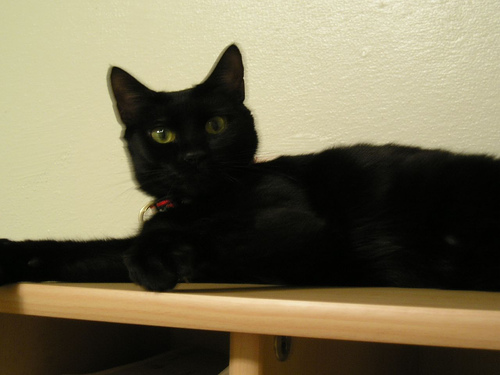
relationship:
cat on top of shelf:
[1, 44, 498, 295] [0, 277, 499, 352]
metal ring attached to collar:
[140, 202, 158, 223] [150, 197, 195, 209]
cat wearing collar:
[1, 44, 498, 295] [150, 197, 195, 209]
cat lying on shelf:
[1, 44, 498, 295] [0, 277, 499, 352]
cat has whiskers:
[1, 44, 498, 295] [98, 171, 181, 198]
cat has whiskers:
[1, 44, 498, 295] [207, 145, 286, 163]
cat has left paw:
[1, 44, 498, 295] [122, 213, 182, 293]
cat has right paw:
[1, 44, 498, 295] [1, 237, 138, 283]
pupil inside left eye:
[212, 118, 219, 131] [204, 116, 227, 136]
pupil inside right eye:
[160, 132, 169, 142] [149, 127, 176, 143]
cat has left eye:
[1, 44, 498, 295] [204, 116, 227, 136]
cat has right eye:
[1, 44, 498, 295] [149, 127, 176, 143]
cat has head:
[1, 44, 498, 295] [116, 85, 258, 196]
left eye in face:
[204, 116, 227, 136] [142, 113, 236, 193]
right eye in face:
[149, 127, 176, 143] [142, 113, 236, 193]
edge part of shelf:
[1, 281, 500, 350] [0, 277, 499, 352]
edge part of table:
[1, 281, 500, 350] [1, 279, 500, 372]